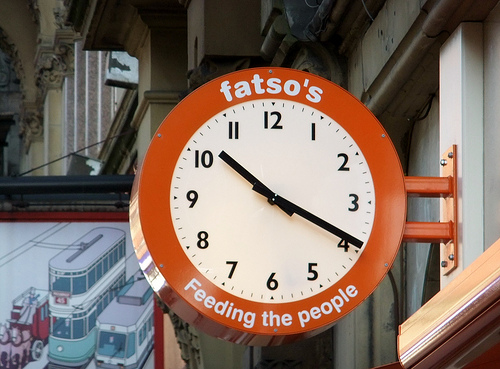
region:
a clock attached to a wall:
[114, 62, 465, 346]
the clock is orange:
[117, 66, 456, 359]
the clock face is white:
[160, 99, 380, 304]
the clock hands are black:
[215, 141, 365, 260]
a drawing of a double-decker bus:
[41, 220, 124, 366]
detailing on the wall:
[0, 4, 100, 151]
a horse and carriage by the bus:
[0, 274, 47, 364]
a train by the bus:
[87, 265, 165, 367]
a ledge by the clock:
[393, 237, 498, 367]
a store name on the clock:
[211, 59, 331, 109]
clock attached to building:
[129, 62, 456, 346]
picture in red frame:
[4, 211, 166, 367]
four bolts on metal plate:
[439, 144, 459, 275]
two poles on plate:
[407, 173, 453, 243]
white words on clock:
[182, 72, 361, 330]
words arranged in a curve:
[216, 71, 322, 105]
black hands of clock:
[215, 147, 363, 247]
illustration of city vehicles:
[48, 228, 145, 367]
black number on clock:
[305, 259, 320, 281]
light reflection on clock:
[127, 194, 162, 296]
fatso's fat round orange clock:
[116, 57, 418, 351]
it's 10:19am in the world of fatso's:
[167, 106, 383, 293]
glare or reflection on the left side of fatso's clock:
[109, 132, 187, 349]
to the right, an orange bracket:
[393, 174, 455, 245]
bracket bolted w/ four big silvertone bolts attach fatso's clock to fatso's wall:
[432, 140, 462, 281]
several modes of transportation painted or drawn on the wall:
[2, 220, 149, 367]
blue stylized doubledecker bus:
[42, 221, 129, 364]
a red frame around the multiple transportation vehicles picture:
[2, 211, 167, 366]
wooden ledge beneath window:
[382, 239, 499, 367]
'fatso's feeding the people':
[175, 57, 372, 337]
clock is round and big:
[142, 67, 382, 337]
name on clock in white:
[206, 80, 342, 113]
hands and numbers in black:
[180, 131, 374, 251]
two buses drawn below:
[46, 227, 146, 364]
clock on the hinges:
[441, 184, 467, 274]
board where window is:
[396, 265, 498, 355]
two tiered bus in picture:
[51, 245, 105, 356]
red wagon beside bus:
[0, 286, 50, 340]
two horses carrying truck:
[0, 331, 40, 363]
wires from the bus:
[7, 224, 83, 255]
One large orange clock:
[126, 60, 406, 344]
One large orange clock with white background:
[120, 50, 410, 348]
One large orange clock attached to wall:
[126, 56, 453, 338]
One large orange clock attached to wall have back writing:
[125, 56, 420, 361]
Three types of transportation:
[0, 227, 140, 362]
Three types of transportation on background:
[0, 230, 135, 365]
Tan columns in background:
[32, 32, 137, 175]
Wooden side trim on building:
[398, 231, 496, 366]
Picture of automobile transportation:
[50, 225, 145, 365]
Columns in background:
[8, 10, 183, 179]